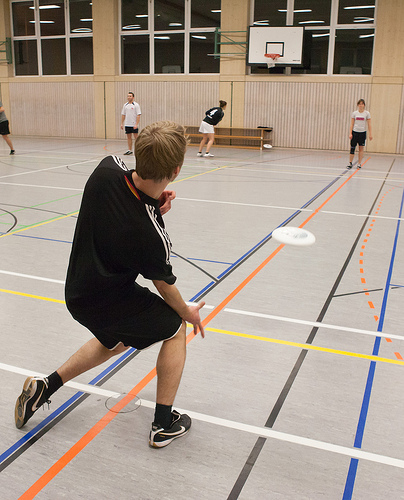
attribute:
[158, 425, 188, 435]
logo — white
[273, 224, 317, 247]
frisbee — white, round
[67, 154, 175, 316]
shirt — black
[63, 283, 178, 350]
shorts — black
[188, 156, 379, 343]
line — orange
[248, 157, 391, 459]
line — black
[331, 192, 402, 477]
line — blue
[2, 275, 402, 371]
line — yellow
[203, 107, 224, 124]
shirt — black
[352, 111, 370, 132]
top — gray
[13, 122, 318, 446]
person — playing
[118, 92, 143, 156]
man — standing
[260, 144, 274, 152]
frisbee — thrown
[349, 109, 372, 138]
shirt — white, gray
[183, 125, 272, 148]
bench — wooden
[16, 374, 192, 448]
shoes — black, white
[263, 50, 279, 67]
hoop — orange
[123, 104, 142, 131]
shirt — gray, white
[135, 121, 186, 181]
hair — brown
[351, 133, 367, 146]
shorts — black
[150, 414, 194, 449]
shoe — white, black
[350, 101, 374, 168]
woman — standing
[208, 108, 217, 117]
design — white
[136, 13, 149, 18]
light — reflected